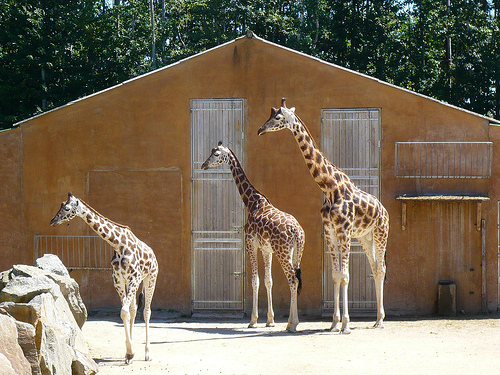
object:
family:
[49, 97, 390, 366]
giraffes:
[256, 97, 391, 336]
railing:
[394, 141, 494, 180]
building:
[0, 28, 500, 316]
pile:
[0, 253, 99, 375]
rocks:
[0, 252, 102, 375]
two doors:
[188, 98, 382, 312]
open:
[335, 128, 377, 161]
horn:
[280, 97, 288, 108]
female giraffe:
[199, 140, 306, 333]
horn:
[67, 191, 75, 199]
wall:
[38, 130, 157, 167]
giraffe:
[48, 192, 159, 368]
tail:
[136, 281, 146, 312]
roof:
[0, 32, 500, 131]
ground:
[343, 339, 500, 373]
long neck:
[78, 199, 119, 248]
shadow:
[114, 324, 267, 336]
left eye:
[65, 207, 71, 211]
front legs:
[118, 275, 139, 360]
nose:
[49, 219, 57, 225]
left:
[17, 194, 46, 235]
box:
[437, 280, 458, 317]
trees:
[0, 0, 500, 129]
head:
[49, 191, 77, 228]